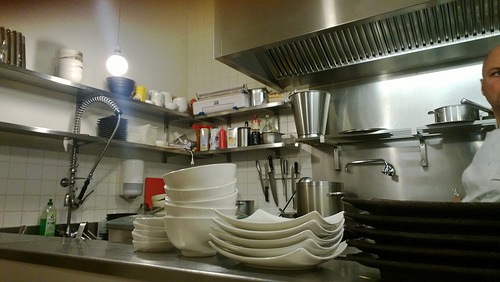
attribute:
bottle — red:
[214, 119, 235, 155]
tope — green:
[45, 192, 61, 211]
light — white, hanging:
[97, 45, 148, 88]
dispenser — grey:
[118, 147, 162, 224]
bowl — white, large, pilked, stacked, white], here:
[171, 153, 248, 194]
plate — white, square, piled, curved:
[218, 194, 359, 237]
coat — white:
[449, 109, 497, 219]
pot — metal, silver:
[278, 80, 334, 150]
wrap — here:
[173, 78, 271, 120]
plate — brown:
[338, 181, 461, 239]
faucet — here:
[57, 160, 101, 220]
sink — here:
[28, 199, 134, 274]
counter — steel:
[13, 220, 88, 275]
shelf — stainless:
[13, 118, 120, 159]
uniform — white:
[450, 160, 498, 191]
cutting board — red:
[144, 164, 181, 253]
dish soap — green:
[30, 189, 64, 239]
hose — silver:
[46, 87, 113, 239]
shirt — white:
[463, 130, 487, 205]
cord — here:
[101, 12, 143, 49]